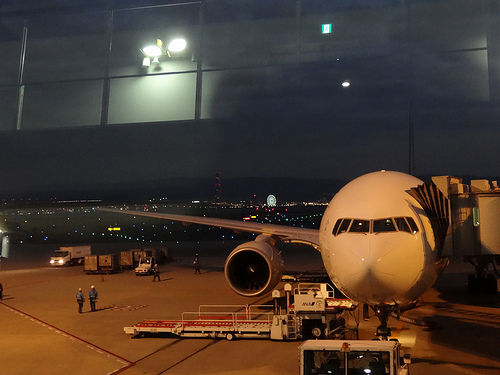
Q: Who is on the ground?
A: Airport employees.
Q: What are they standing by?
A: A plane.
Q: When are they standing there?
A: At night.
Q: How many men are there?
A: Four.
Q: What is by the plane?
A: A truck.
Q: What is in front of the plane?
A: Another truck.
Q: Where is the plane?
A: On the runway.